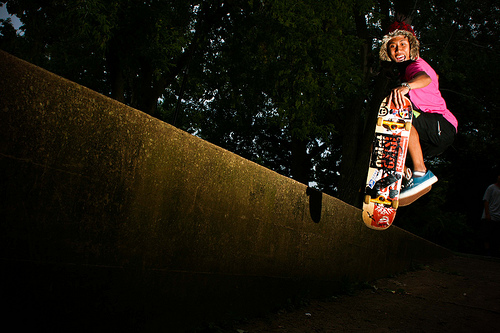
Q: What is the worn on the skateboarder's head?
A: A hat.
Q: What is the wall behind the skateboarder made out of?
A: Cement.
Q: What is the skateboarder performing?
A: A trick.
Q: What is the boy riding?
A: A skateboard.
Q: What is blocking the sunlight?
A: Large trees.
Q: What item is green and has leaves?
A: A tree.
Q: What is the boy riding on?
A: A skateboard.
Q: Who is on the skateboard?
A: A boy.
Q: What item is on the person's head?
A: A hat.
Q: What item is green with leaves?
A: A tree.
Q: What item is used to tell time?
A: A watch.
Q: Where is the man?
A: On a skateboard.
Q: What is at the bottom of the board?
A: The board has stickers on the bottom.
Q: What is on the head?
A: Fur hat.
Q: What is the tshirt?
A: Pink.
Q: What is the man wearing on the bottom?
A: Shorts.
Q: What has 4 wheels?
A: Skateboard.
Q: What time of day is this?
A: Sunset.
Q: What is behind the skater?
A: Trees.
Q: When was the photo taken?
A: Night.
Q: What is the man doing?
A: Skating.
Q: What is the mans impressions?
A: Happy.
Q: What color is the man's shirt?
A: Pink.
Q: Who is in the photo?
A: A man.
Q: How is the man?
A: In motion.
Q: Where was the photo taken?
A: On the street.